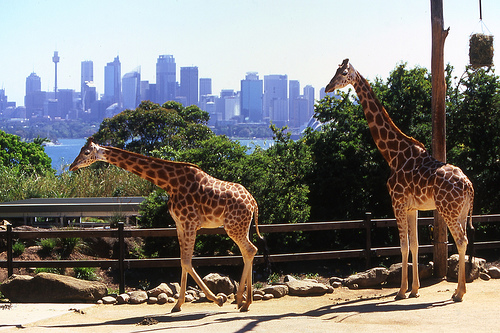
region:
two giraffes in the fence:
[54, 33, 498, 296]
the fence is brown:
[29, 211, 160, 279]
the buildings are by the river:
[6, 43, 299, 138]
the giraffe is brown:
[65, 128, 252, 281]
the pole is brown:
[419, 13, 460, 281]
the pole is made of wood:
[419, 21, 464, 232]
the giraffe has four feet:
[398, 188, 467, 319]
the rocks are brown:
[337, 253, 487, 305]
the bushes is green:
[160, 113, 332, 197]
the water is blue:
[47, 135, 72, 160]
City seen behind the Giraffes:
[0, 48, 362, 138]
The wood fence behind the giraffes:
[2, 209, 497, 294]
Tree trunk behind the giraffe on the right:
[418, 0, 458, 280]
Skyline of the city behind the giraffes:
[20, 48, 337, 97]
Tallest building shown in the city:
[46, 46, 62, 93]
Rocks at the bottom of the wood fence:
[2, 249, 498, 305]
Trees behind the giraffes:
[3, 59, 497, 223]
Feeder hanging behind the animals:
[462, 28, 498, 71]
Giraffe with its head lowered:
[58, 121, 265, 312]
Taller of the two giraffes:
[323, 53, 477, 303]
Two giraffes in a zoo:
[62, 79, 494, 315]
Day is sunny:
[2, 6, 496, 327]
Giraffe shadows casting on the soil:
[40, 289, 458, 329]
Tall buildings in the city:
[2, 37, 347, 136]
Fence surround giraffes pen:
[0, 210, 498, 290]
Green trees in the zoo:
[0, 57, 498, 222]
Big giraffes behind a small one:
[307, 54, 498, 307]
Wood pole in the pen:
[421, 3, 452, 283]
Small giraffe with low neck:
[61, 130, 271, 321]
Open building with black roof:
[7, 181, 152, 225]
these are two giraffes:
[55, 55, 481, 302]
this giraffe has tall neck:
[323, 59, 424, 156]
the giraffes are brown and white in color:
[71, 51, 481, 310]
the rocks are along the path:
[2, 271, 479, 298]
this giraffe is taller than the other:
[323, 48, 476, 303]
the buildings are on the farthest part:
[0, 50, 317, 103]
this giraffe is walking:
[71, 140, 275, 307]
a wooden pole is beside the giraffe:
[431, 0, 446, 162]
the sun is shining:
[7, 305, 69, 315]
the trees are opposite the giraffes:
[191, 131, 371, 156]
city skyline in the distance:
[11, 42, 317, 144]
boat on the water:
[9, 132, 69, 158]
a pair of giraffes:
[50, 48, 480, 314]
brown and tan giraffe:
[67, 130, 269, 307]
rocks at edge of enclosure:
[10, 245, 495, 298]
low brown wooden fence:
[10, 210, 492, 280]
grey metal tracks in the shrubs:
[7, 189, 159, 224]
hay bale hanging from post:
[465, 21, 499, 77]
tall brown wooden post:
[415, 6, 472, 288]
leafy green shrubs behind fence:
[144, 115, 491, 227]